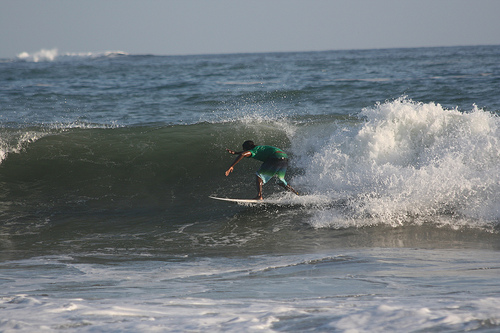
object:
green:
[256, 147, 278, 159]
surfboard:
[207, 194, 335, 204]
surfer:
[208, 139, 334, 204]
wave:
[3, 96, 500, 234]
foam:
[280, 93, 499, 235]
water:
[3, 47, 499, 332]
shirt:
[247, 145, 288, 163]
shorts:
[256, 156, 288, 185]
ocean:
[0, 42, 498, 332]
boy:
[224, 140, 299, 201]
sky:
[0, 0, 499, 56]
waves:
[16, 48, 56, 64]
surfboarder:
[225, 140, 300, 200]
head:
[242, 140, 253, 151]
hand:
[224, 166, 234, 177]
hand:
[225, 148, 237, 156]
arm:
[230, 150, 253, 167]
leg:
[276, 170, 298, 196]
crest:
[4, 113, 305, 158]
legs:
[252, 169, 278, 202]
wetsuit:
[245, 144, 289, 187]